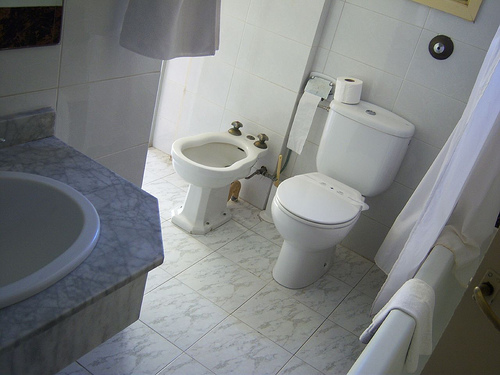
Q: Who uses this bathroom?
A: The owners.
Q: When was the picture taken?
A: Daylight.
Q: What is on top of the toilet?
A: Toilet paper.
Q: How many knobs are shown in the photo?
A: 2.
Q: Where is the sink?
A: Front of toilet.